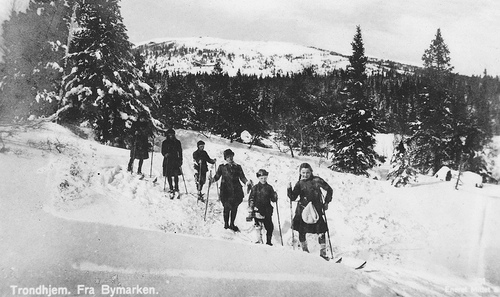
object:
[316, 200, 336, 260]
ski pole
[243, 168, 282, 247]
skier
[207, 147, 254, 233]
skier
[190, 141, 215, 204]
skier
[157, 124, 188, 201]
skier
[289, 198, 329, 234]
skirt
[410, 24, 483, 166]
trees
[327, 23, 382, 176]
trees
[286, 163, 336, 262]
girl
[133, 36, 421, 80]
snow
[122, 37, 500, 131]
mountain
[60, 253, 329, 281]
tracks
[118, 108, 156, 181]
skiers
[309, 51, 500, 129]
mountainside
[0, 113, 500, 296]
snow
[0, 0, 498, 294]
mountainside